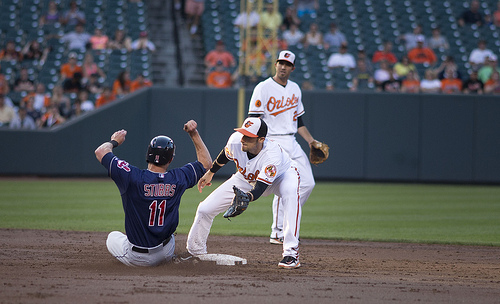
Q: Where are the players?
A: On dirt.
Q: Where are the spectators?
A: Behind the wall.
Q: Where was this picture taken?
A: Baseball field.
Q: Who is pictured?
A: Three men in the foreground and groups of people in the background.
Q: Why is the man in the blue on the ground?
A: He was sliding to reach the base.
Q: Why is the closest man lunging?
A: He is trying to catch the baseball.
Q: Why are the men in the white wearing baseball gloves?
A: To catch the baseball.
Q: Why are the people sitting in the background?
A: They are watching the baseball game.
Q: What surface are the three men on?
A: Dirt.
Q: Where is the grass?
A: Behind the dirt.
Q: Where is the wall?
A: Behind the grass.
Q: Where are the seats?
A: On the other side of the wall.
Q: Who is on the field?
A: Three players.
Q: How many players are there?
A: Three.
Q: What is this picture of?
A: Baseball players.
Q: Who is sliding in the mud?
A: Player Number 11.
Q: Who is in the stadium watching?
A: Fans of the teams.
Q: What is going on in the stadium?
A: A baseball game.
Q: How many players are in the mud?
A: One.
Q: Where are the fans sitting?
A: The bleachers.